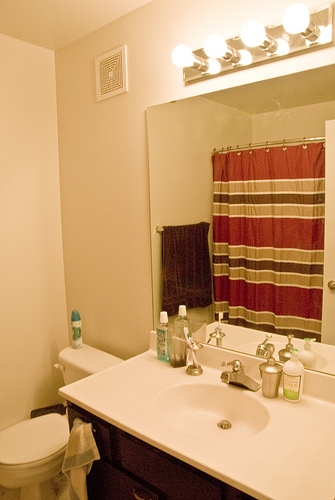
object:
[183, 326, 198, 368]
toothbrush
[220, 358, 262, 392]
fixture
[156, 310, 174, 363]
bottle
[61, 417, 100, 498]
towel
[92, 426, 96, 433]
handle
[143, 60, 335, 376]
mirror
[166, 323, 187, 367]
cup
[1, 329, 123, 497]
toilet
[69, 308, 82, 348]
can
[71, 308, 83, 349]
aerosol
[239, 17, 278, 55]
bulbs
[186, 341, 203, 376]
holder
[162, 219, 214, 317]
towel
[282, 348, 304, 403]
bottle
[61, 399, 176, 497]
cabinets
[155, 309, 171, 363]
mouth wash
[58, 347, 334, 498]
counter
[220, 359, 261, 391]
faucet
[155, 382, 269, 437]
sink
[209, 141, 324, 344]
shower curtain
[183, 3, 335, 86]
fixture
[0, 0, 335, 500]
bathroom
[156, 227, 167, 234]
rack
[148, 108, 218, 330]
wall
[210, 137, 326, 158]
rod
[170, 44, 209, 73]
bulb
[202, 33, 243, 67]
bulb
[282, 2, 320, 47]
bulb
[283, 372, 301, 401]
lotion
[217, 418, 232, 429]
drain